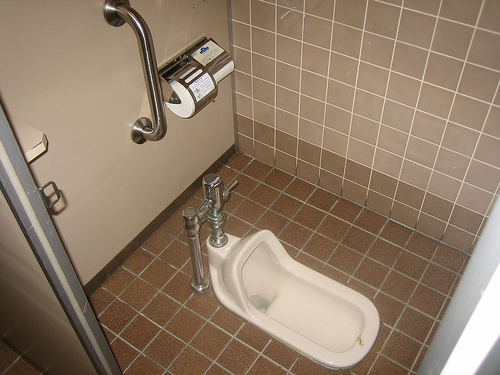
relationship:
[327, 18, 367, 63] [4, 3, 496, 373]
tile on restroom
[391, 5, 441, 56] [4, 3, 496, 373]
tile on restroom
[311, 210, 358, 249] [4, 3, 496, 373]
tile in restroom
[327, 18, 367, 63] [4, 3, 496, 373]
tile in restroom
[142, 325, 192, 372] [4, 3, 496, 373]
tile on restroom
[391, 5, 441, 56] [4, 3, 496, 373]
tile in restroom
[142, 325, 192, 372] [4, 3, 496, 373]
tile in restroom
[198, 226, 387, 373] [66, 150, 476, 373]
urinal on floor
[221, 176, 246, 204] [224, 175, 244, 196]
handle for flashing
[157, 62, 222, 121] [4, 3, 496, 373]
dispenser in restroom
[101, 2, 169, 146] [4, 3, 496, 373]
handicap bar in restroom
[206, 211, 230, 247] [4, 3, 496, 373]
water pipe in restroom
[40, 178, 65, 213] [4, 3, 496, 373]
latch in restroom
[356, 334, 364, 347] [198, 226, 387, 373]
stain in urinal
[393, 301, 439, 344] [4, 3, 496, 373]
tile in restroom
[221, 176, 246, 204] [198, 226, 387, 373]
handle to flush of urinal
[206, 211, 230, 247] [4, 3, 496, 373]
water pipe of restroom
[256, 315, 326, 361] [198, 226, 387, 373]
rim of urinal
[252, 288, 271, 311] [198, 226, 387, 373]
hole in urinal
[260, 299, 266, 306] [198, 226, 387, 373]
water in urinal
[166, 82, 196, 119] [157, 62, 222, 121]
toilet paper in dispenser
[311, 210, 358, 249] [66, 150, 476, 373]
tile in floor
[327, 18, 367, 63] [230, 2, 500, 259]
tile on wall